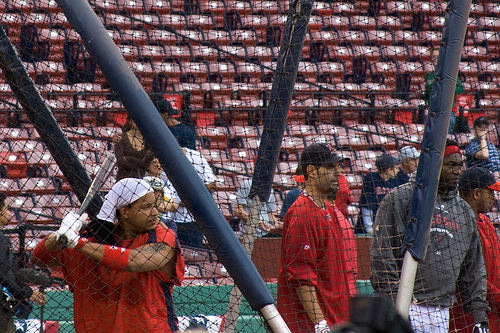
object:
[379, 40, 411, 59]
seat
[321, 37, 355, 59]
seat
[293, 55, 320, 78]
seat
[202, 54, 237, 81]
seat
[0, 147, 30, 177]
seat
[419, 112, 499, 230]
cap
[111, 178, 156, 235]
head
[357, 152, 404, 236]
spectators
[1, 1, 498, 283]
stands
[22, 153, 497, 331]
team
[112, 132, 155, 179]
shirt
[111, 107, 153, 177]
woman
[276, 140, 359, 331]
man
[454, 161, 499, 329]
players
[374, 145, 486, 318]
players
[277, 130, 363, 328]
players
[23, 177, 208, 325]
players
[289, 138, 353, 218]
man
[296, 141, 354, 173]
cap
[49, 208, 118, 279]
gloves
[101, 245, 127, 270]
band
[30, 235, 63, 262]
band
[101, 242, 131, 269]
armband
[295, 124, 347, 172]
hat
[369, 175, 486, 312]
sweatshirt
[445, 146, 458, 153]
headband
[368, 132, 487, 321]
man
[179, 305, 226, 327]
flag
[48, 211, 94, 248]
gloves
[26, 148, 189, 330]
player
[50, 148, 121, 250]
baseball bat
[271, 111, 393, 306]
man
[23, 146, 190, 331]
man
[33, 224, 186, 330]
red shirt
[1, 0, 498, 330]
netting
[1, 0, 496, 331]
batting cage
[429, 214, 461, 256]
logo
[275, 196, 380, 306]
shirt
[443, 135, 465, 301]
band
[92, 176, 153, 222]
cloth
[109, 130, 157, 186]
shirt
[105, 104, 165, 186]
woman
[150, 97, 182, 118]
hat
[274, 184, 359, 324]
shirt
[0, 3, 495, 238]
stands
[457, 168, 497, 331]
man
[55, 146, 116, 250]
bat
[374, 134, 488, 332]
man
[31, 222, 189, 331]
shirt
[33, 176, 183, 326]
man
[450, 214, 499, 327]
shirt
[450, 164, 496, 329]
man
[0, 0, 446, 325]
fence